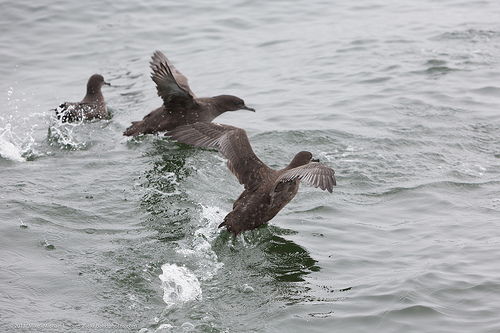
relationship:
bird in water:
[164, 120, 337, 239] [0, 3, 499, 331]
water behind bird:
[0, 3, 499, 331] [164, 120, 337, 239]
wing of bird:
[271, 162, 338, 197] [164, 120, 337, 239]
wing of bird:
[162, 121, 273, 188] [164, 120, 337, 239]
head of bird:
[289, 148, 320, 165] [164, 120, 337, 239]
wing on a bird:
[271, 162, 338, 197] [164, 120, 337, 239]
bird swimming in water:
[164, 120, 337, 239] [0, 3, 499, 331]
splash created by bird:
[158, 204, 271, 303] [164, 120, 337, 239]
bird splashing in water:
[164, 120, 337, 239] [0, 3, 499, 331]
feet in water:
[232, 230, 262, 251] [0, 3, 499, 331]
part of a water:
[433, 1, 497, 51] [0, 3, 499, 331]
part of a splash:
[158, 260, 202, 308] [158, 204, 271, 303]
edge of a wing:
[195, 120, 245, 132] [162, 121, 273, 188]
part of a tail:
[122, 125, 133, 138] [123, 114, 151, 136]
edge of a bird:
[230, 191, 246, 210] [164, 120, 337, 239]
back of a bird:
[221, 164, 290, 229] [164, 120, 337, 239]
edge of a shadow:
[274, 232, 317, 261] [215, 222, 322, 287]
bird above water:
[164, 120, 337, 239] [0, 3, 499, 331]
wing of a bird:
[271, 162, 338, 197] [164, 120, 337, 239]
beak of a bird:
[312, 156, 321, 163] [164, 120, 337, 239]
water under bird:
[0, 3, 499, 331] [164, 120, 337, 239]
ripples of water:
[408, 58, 458, 77] [0, 3, 499, 331]